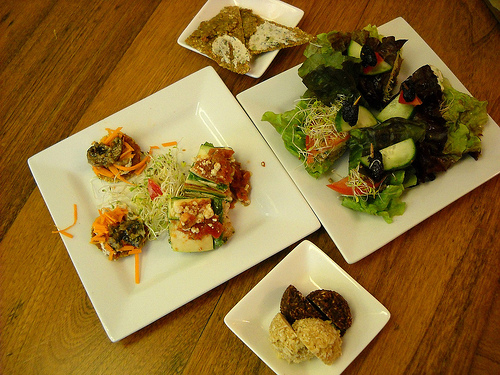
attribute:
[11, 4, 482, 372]
plates — white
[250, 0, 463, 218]
salad — small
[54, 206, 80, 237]
carrot — orange 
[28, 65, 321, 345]
plate — white , white and square, large, square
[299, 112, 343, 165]
tomato — red 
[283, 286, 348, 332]
cookie — white and brown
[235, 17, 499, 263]
plate — large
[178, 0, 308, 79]
plate — small , square, white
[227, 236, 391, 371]
plate — square , small, white 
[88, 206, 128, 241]
carrot — orange 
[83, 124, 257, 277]
sandwiches — small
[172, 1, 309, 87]
plate — small, white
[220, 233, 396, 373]
plate — square, white, small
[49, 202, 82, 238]
slice — orange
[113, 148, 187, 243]
lettuce — green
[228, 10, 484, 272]
plate — square, white, large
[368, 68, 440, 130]
sandwich — small